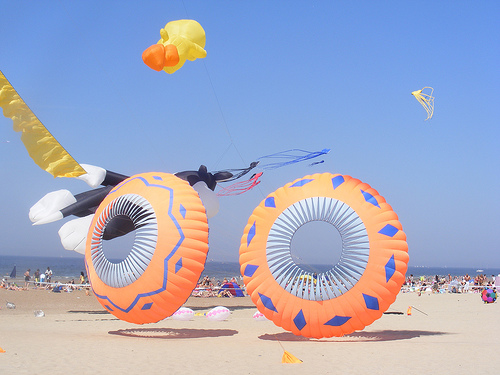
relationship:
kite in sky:
[409, 76, 448, 134] [4, 1, 499, 273]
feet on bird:
[139, 41, 181, 73] [137, 12, 207, 73]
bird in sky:
[137, 12, 207, 73] [4, 1, 499, 273]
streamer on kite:
[264, 148, 311, 158] [255, 142, 338, 166]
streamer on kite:
[267, 160, 311, 166] [255, 142, 338, 166]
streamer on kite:
[237, 183, 257, 194] [0, 70, 274, 256]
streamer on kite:
[222, 183, 247, 191] [0, 70, 274, 256]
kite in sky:
[0, 70, 274, 256] [4, 1, 499, 273]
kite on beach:
[252, 168, 406, 330] [5, 273, 495, 365]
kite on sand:
[235, 166, 407, 333] [2, 282, 499, 370]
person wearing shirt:
[44, 263, 53, 284] [43, 268, 53, 277]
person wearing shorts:
[24, 269, 33, 283] [22, 274, 31, 284]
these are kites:
[74, 170, 425, 337] [65, 175, 419, 333]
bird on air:
[137, 12, 207, 73] [81, 7, 329, 116]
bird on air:
[137, 12, 207, 73] [138, 15, 213, 76]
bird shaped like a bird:
[137, 12, 207, 73] [137, 12, 207, 73]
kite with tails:
[409, 85, 438, 123] [424, 80, 435, 126]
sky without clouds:
[4, 1, 499, 273] [4, 24, 493, 264]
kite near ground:
[234, 159, 420, 348] [238, 313, 430, 359]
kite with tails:
[256, 145, 331, 169] [262, 145, 318, 171]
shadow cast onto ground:
[104, 322, 243, 340] [82, 320, 262, 363]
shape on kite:
[359, 290, 383, 314] [235, 166, 407, 333]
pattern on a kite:
[296, 200, 327, 219] [235, 166, 407, 333]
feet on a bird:
[139, 41, 181, 73] [137, 12, 207, 73]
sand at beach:
[27, 299, 490, 361] [11, 283, 498, 373]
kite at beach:
[409, 85, 438, 123] [2, 251, 498, 372]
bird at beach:
[137, 12, 207, 73] [2, 251, 498, 372]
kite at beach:
[2, 78, 274, 256] [2, 251, 498, 372]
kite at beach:
[242, 174, 409, 335] [2, 251, 498, 372]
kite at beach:
[84, 173, 204, 325] [2, 251, 498, 372]